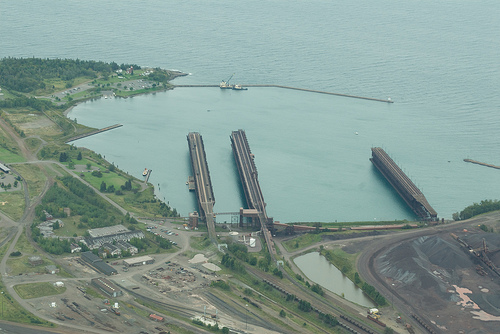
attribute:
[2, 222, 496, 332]
land — small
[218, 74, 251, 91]
boat — parked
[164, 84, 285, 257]
runways — dark gray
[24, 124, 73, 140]
land — bare, brown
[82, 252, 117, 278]
blackroof — black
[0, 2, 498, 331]
picture — outdoors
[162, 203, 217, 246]
tower — tall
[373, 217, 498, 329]
quarry — dark gray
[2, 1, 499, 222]
water — calm, light blue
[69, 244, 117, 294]
building — black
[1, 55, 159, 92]
forest — large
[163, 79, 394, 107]
barrier — long, thin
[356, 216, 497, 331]
tarmac — large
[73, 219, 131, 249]
building — black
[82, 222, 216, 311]
parking — open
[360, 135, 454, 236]
station — docking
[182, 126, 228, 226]
station — docking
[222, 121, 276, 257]
station — sheep, docking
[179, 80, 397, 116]
station — docking, sheep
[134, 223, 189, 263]
cars — parked